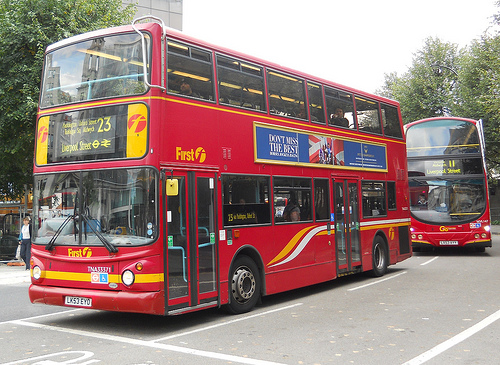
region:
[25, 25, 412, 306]
double decker bus traveling on the road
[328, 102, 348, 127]
person riding on 2nd level of bus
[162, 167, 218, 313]
front doors to double decker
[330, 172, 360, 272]
rear door to double decker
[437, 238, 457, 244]
front license plate of 2nd bus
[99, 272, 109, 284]
wheelchair symbol in front of the bus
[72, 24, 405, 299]
A double-decker bus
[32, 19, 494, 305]
Two double-decker buses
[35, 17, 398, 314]
A red bus on the road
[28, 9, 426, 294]
A red double-decker bus on the road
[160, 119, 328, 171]
Writings on the bus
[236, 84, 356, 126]
People riding the bus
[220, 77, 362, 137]
People inside the bus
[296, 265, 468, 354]
Road with tarmac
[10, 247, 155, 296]
Headlights on the bus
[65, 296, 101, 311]
license plate on bus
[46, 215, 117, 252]
windshield wipers on bus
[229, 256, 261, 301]
a wheel on the bus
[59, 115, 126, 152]
bus number and route of bus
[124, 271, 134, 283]
a light on the bus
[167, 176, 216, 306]
entry door on the bus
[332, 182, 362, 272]
exit door on bus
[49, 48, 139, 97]
window on top tier of bus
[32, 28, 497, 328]
two double decker buses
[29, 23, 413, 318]
Completely visible double decker red bus.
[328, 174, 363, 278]
Last double doors on the side of a bus.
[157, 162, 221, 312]
Double red doors under the word First.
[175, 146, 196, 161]
The orange word First over the double doors.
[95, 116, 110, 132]
The larger yellow number 23 on a bus.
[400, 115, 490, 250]
Not completely visible double decker bus.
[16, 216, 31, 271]
A woman walking in a white shirt and black pants.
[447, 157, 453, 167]
Yellow number 11 on the less visible bus.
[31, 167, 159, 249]
Front bottom windshield on the more visible bus.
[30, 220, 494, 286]
the lights on frtont of the bus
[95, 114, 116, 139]
23 on the front of bus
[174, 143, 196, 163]
fast on the side of bus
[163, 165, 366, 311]
the double doors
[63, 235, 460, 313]
tag on front of bus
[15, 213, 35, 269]
a lady walking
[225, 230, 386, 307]
wheels on the bus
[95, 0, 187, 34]
a building on the left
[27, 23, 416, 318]
Double Decker bus on the street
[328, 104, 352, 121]
passenger looking out of the window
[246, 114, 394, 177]
advertisement on the side of the bus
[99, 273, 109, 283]
handicap sticker on the bus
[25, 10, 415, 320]
large red double decker bus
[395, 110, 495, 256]
large red double decker bus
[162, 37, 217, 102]
window of large red double decker bus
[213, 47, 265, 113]
window of large red double decker bus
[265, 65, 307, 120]
window of large red double decker bus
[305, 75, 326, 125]
window of large red double decker bus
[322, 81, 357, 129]
window of large red double decker bus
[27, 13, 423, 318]
red bus with yellow and white stripes on side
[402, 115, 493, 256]
full front of red bus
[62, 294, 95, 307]
white license plate with black writing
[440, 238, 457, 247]
white license plate with black writing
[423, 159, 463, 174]
black navigation sign with yellow letters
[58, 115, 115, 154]
black navigation sign with yellow letters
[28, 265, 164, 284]
yellow line across front of the red bus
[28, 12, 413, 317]
large red bus with two decks